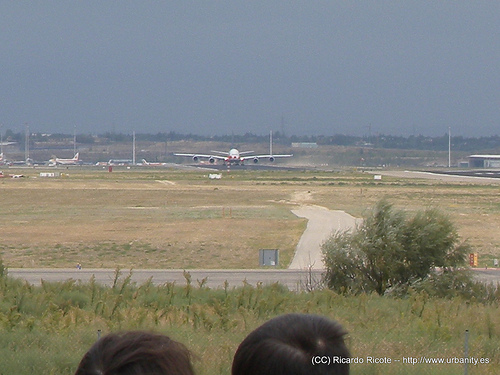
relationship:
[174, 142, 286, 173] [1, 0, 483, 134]
plane near sky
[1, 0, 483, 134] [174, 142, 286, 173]
sky above plane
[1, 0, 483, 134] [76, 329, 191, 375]
sky above man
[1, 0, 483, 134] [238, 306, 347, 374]
sky above hair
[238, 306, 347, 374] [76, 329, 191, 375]
hair near man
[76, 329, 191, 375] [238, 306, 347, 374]
man near hair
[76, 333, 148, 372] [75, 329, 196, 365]
man has hair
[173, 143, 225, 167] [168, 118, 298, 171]
wing of plane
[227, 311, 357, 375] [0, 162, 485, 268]
people looking in field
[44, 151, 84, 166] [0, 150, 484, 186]
airplane at an airport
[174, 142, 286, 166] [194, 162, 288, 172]
plane landing on dirt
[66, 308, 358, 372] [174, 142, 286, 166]
people are watching plane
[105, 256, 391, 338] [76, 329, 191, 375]
grass in front of man